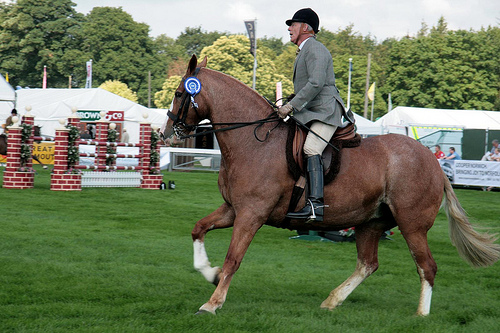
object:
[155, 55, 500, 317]
horse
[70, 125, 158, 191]
jump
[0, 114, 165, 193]
course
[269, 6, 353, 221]
man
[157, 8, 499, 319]
dressage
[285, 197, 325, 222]
left stirrup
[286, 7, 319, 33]
hat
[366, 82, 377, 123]
flag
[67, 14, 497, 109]
distance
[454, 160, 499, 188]
sign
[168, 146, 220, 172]
fence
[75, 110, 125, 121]
sign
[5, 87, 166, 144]
tent